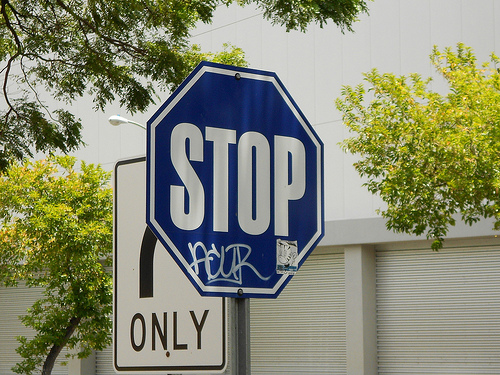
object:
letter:
[271, 133, 308, 235]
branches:
[11, 0, 363, 130]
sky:
[0, 1, 498, 224]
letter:
[169, 122, 205, 230]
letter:
[205, 125, 236, 234]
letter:
[237, 130, 271, 235]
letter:
[274, 135, 302, 235]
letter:
[185, 241, 272, 286]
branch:
[28, 222, 83, 308]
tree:
[327, 40, 498, 257]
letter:
[129, 312, 146, 352]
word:
[123, 305, 209, 354]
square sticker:
[275, 237, 301, 275]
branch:
[349, 73, 491, 225]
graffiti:
[161, 219, 278, 310]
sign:
[83, 21, 383, 334]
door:
[242, 251, 344, 371]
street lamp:
[81, 89, 196, 157]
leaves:
[331, 39, 498, 254]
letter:
[162, 117, 202, 244]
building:
[1, 204, 495, 371]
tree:
[4, 6, 373, 242]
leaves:
[8, 7, 139, 83]